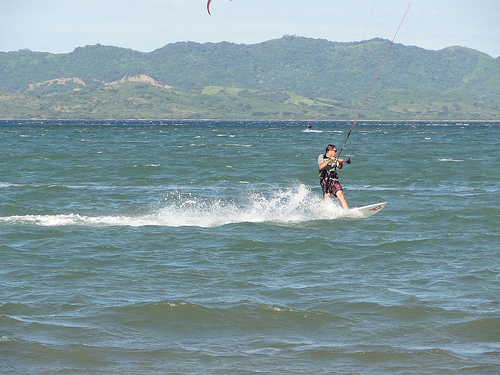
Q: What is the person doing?
A: Water skiing.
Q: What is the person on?
A: Skis.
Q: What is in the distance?
A: Mountains.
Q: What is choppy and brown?
A: The water.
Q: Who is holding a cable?
A: Man in water.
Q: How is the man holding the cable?
A: With hands.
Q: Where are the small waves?
A: On water.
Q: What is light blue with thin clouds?
A: The sky.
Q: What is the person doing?
A: Windsurfing.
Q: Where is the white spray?
A: Behind the surfer.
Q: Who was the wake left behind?
A: The windsurfer.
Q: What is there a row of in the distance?
A: Mountains.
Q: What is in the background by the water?
A: Hills.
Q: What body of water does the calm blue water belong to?
A: The ocean.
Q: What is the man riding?
A: Wakeboard.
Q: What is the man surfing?
A: Water.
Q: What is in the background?
A: Mountains.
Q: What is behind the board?
A: Ripples.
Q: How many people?
A: Two.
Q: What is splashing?
A: Water.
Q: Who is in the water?
A: People.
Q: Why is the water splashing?
A: Waves.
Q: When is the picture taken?
A: Daytime.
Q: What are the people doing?
A: Parasailing.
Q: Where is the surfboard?
A: In the water.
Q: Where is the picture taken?
A: At a lake.